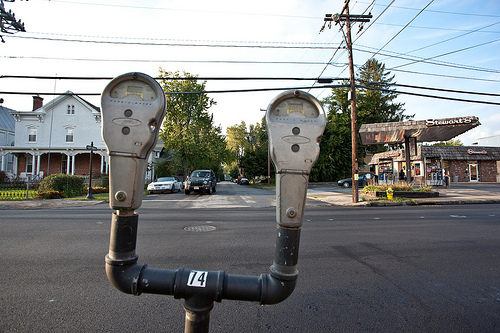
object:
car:
[337, 176, 373, 189]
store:
[365, 145, 499, 186]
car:
[146, 176, 180, 194]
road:
[0, 199, 500, 333]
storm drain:
[421, 203, 446, 207]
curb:
[360, 196, 500, 206]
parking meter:
[99, 70, 164, 210]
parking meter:
[266, 89, 328, 228]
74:
[187, 269, 207, 287]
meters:
[93, 69, 175, 276]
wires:
[0, 73, 500, 99]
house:
[1, 89, 163, 201]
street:
[0, 185, 499, 332]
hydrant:
[386, 184, 397, 202]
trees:
[155, 68, 218, 189]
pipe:
[102, 212, 303, 329]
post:
[266, 142, 271, 184]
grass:
[0, 186, 47, 201]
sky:
[0, 0, 499, 119]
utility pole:
[324, 0, 375, 204]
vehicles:
[182, 169, 217, 195]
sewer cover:
[182, 223, 218, 233]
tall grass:
[371, 181, 379, 193]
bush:
[37, 173, 88, 196]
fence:
[0, 176, 88, 203]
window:
[65, 132, 75, 143]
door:
[468, 160, 479, 182]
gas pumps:
[358, 116, 499, 187]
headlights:
[164, 184, 169, 186]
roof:
[353, 114, 481, 143]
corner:
[448, 172, 499, 197]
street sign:
[87, 141, 93, 199]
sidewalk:
[0, 198, 111, 209]